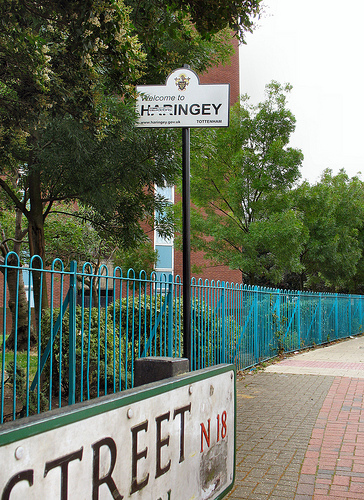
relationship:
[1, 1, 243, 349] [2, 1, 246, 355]
wall on building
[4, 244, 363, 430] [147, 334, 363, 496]
fence panel along a sidewalk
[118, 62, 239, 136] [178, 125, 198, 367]
sign on a pole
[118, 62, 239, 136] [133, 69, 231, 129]
sign has trim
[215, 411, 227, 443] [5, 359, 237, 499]
numbers on sign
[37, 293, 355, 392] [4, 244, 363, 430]
bushes behind fence panel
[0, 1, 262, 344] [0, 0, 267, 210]
tree has leaves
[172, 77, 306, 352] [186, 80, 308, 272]
tree has leaves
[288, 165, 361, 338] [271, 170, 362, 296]
tree has leaves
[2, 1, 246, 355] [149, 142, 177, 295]
building has window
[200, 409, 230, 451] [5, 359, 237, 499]
lettering on sign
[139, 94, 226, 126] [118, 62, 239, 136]
lettering on sign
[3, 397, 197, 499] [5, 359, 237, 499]
lettering on sign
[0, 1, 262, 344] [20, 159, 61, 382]
tree has trunk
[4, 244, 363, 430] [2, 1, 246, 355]
fence panel around building